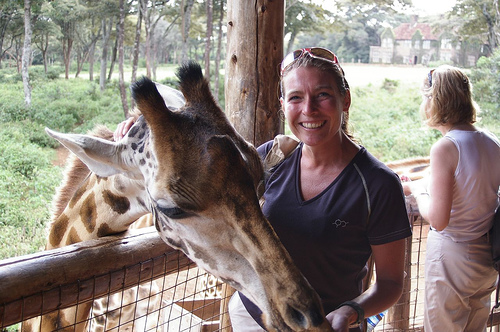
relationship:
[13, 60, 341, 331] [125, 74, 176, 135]
giraffe has horn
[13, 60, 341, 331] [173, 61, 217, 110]
giraffe has horn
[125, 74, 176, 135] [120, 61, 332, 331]
horn on head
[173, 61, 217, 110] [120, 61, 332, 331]
horn on head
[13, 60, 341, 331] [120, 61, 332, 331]
giraffe has head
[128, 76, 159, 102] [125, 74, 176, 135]
hair on top of horn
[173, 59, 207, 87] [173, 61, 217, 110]
hair on top of horn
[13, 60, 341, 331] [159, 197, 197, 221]
giraffe has eye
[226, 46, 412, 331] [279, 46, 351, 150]
woman has head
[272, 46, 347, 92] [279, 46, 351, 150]
sunglasses are on top of head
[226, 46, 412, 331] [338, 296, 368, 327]
woman wearing watch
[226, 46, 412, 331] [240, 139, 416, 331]
woman wearing shirt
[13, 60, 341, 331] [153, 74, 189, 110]
giraffe has ear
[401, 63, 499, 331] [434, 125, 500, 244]
woman wearing shirt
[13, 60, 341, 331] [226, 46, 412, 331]
giraffe next to woman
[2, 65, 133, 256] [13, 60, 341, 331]
bushes are behind giraffe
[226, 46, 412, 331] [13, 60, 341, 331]
woman feeding giraffe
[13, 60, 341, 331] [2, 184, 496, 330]
giraffe behind fence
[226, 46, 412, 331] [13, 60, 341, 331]
woman petting giraffe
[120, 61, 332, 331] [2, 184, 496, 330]
head over fence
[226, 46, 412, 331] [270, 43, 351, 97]
woman has hair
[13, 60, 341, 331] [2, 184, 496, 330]
giraffe leaning over fence